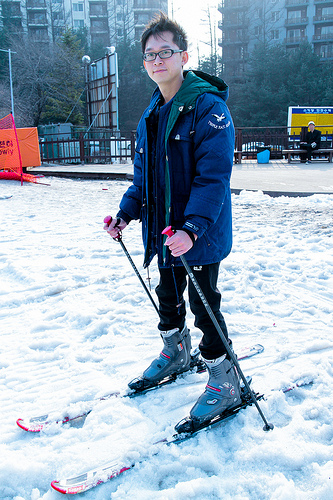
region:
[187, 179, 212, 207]
part of a jacket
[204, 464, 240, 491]
part of a snow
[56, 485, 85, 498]
edge of a skater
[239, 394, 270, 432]
part of a hooker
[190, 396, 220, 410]
part of a boot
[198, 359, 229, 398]
part of a boot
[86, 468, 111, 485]
top of a skater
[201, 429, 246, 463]
part of a snow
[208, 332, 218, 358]
part of a trouser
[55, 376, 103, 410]
part of some lines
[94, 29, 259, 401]
this is a man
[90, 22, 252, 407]
the man is standing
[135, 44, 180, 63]
he is wearing spectacles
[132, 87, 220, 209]
this is a jacket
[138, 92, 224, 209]
the jacket is heavy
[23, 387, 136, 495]
he is wearing skiis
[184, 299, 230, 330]
this is a stick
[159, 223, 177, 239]
the stick has red handle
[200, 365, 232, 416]
the shoe is big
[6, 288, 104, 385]
place is full of snow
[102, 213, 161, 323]
a ski pole with a red handle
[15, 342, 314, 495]
a pair of skis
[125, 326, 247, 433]
a pair of gray boots attached to skis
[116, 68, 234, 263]
a blue hooded jacket being worn by a young man in skis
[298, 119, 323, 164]
a man sitting on a bench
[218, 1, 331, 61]
the top floors of an apartment building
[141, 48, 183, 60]
a pair of eyeglasses with a black frame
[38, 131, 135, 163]
a brown fence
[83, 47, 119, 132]
the back of a large sign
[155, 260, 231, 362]
black pants worn by a young man on skis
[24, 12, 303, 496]
a young boy on ski's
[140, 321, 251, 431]
grey ski boots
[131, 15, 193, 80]
young man wearing black glasses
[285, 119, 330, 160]
a person sitting on a bench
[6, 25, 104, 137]
a group of trees some without leafs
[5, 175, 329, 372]
a ground full of snow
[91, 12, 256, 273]
boy in a blue jacket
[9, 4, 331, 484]
a boy trying to ski in the city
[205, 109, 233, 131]
white bird on the arm of the jacket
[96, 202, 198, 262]
red handles on the ski poles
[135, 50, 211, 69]
Man is wearing glasses on face.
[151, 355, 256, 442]
Man has gray boots on feet.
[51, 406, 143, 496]
Red and white skis on feet.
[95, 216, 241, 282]
Man holding ski poles.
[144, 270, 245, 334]
Man wearing black pants.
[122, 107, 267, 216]
Man wearing blue coat.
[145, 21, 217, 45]
Man has dark hair.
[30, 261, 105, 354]
Ground is covered in snow.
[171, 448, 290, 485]
Snow on ground is white.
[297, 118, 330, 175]
Person sitting on bench in background.